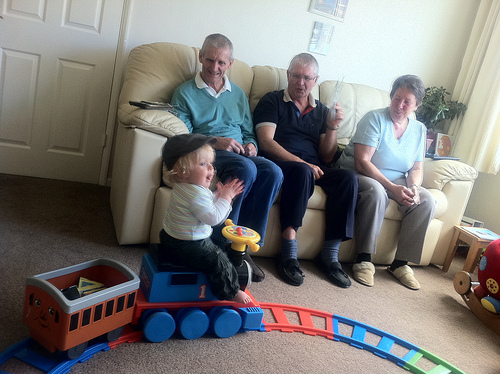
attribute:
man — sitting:
[167, 34, 283, 284]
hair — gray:
[198, 30, 233, 63]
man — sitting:
[254, 53, 357, 291]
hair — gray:
[286, 50, 320, 77]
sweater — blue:
[167, 78, 258, 150]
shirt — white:
[194, 69, 232, 96]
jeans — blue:
[212, 144, 284, 250]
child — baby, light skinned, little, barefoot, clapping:
[158, 130, 252, 303]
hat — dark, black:
[161, 130, 216, 169]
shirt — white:
[161, 183, 231, 241]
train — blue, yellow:
[22, 217, 263, 360]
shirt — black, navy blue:
[251, 88, 328, 169]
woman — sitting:
[333, 72, 435, 291]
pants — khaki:
[354, 174, 433, 266]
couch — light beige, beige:
[106, 40, 479, 266]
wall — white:
[105, 1, 499, 232]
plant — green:
[413, 85, 467, 135]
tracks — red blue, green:
[0, 299, 468, 373]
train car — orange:
[22, 256, 140, 359]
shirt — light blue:
[334, 108, 427, 184]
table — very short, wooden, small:
[440, 224, 499, 274]